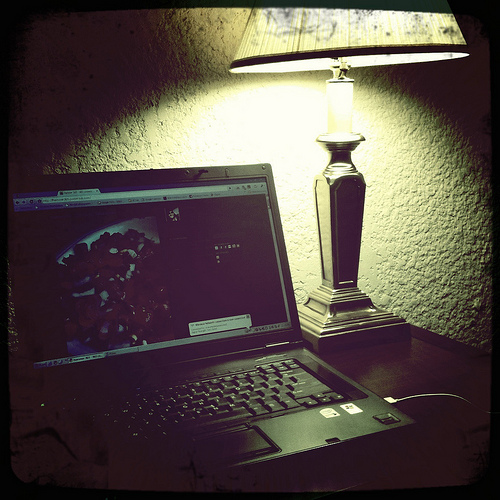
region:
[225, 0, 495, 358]
lamp powered on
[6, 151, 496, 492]
laptop sitting on desk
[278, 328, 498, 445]
white USB cord hooked into laptop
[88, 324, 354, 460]
black keyboard on laptop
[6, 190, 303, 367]
internet opened on laptop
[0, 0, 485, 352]
light casting shadows on wall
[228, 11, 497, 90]
lamp shade with black design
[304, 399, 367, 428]
stickers on black laptop computer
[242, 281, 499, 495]
wooden desk with lamp and laptop sitting on it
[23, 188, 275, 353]
picture of food on laptop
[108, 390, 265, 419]
A computer key board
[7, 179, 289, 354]
Windows running chrome browser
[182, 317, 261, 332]
Windows update pop up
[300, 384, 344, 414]
Arrow keys on computer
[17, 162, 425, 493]
Black thinkpad lap top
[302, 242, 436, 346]
The base of a lamp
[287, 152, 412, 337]
Thr tunk of a lamp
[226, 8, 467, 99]
The bottom of lamp shade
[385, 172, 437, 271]
White ridged wall plaster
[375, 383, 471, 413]
White charger cord for device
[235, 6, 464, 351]
lamp sitting on desk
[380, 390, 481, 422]
corded plugged into laptop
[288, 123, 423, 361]
base of lamp on desk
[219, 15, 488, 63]
printed lampshade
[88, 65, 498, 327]
light from lamp on wall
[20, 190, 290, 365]
screen of black laptop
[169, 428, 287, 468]
black trackpad of laptop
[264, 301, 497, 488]
brown desk laptop and lamp are on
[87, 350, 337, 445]
built in keyboard of laptop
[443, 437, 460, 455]
part of a table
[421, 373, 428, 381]
edge of a table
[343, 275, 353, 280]
part of a lamp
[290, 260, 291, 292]
edge of a laptop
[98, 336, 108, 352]
part of a screen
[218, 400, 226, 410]
part of a keypad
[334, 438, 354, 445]
edge of a laptop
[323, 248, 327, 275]
edge of a laptop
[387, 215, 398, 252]
side of a wall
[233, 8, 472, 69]
blue and white lamp shade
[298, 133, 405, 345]
grey metal lamp on desk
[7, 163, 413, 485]
black laptop on table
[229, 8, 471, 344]
lit lamp on table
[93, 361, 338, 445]
computer laptop key board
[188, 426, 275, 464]
touch pad mouse on laptop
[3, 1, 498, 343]
white spackled room wall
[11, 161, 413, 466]
laptop sitting on table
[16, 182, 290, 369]
laptop computer monitor screen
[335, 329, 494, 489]
dark wooden table top